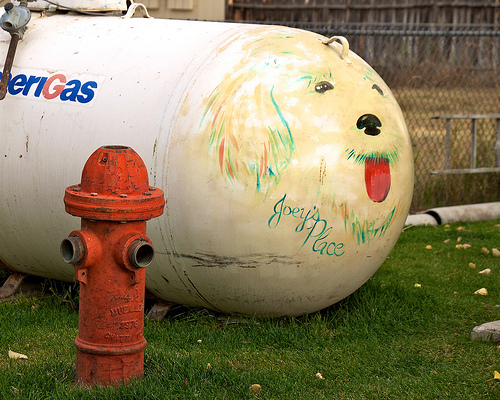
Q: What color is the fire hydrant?
A: Red.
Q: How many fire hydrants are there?
A: One.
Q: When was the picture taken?
A: Daytime.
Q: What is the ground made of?
A: Grass.